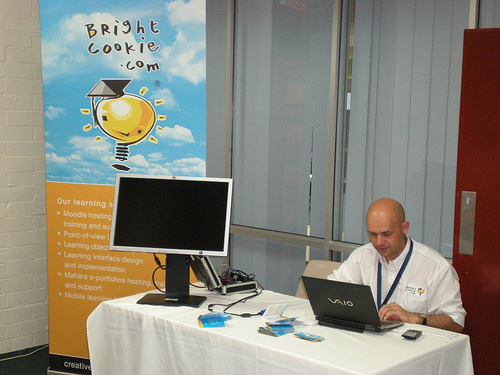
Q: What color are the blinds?
A: White.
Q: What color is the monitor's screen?
A: Black.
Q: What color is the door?
A: Red.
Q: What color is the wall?
A: White.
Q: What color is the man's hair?
A: He's bald.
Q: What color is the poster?
A: Blue and orange.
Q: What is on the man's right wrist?
A: Black watch.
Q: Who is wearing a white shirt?
A: A bald man.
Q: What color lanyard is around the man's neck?
A: Blue.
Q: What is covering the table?
A: White table cloth.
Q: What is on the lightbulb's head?
A: Graduation cap.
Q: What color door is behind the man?
A: Red.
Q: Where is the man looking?
A: At VAIO laptop.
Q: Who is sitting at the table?
A: Bald man.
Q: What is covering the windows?
A: White blinds.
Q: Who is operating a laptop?
A: A man.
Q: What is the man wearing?
A: A lanyard.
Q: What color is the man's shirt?
A: White.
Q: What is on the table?
A: A monitor.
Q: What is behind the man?
A: Windows.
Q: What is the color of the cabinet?
A: Red.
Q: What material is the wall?
A: Brick.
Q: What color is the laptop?
A: Black.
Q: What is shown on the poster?
A: A light bulb.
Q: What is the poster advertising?
A: A webpage.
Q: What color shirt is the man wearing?
A: White.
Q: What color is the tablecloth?
A: White.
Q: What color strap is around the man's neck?
A: Blue.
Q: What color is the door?
A: Red.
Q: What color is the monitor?
A: Gray.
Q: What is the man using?
A: A laptop.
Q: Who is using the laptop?
A: The man.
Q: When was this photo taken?
A: During the day.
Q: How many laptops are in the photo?
A: 1.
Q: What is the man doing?
A: Using the laptop.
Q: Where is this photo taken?
A: A reception area.